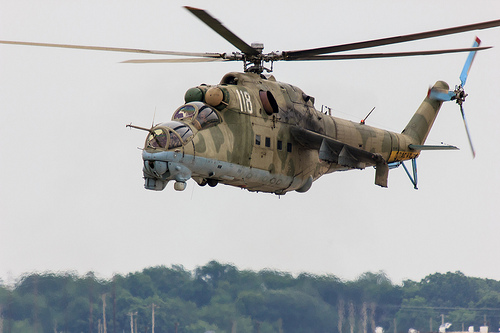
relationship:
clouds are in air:
[0, 3, 500, 292] [2, 1, 495, 278]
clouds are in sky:
[0, 3, 500, 292] [44, 107, 218, 269]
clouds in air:
[0, 3, 500, 292] [2, 1, 495, 278]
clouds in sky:
[0, 3, 500, 292] [390, 197, 460, 239]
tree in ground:
[344, 281, 409, 331] [4, 321, 497, 328]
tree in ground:
[223, 280, 300, 331] [3, 320, 496, 330]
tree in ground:
[85, 279, 122, 331] [0, 325, 493, 332]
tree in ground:
[390, 257, 496, 323] [1, 317, 498, 329]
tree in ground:
[37, 275, 82, 331] [6, 318, 497, 328]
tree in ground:
[363, 270, 387, 332] [6, 318, 497, 328]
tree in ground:
[90, 279, 120, 331] [6, 318, 497, 328]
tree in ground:
[143, 292, 165, 331] [6, 318, 497, 328]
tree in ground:
[473, 288, 498, 331] [6, 318, 497, 328]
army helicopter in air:
[0, 4, 499, 196] [2, 1, 495, 278]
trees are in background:
[0, 259, 498, 331] [1, 263, 498, 331]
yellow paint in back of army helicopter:
[389, 145, 420, 162] [0, 4, 499, 196]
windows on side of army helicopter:
[243, 126, 285, 155] [0, 4, 499, 196]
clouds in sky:
[0, 3, 500, 292] [42, 84, 124, 181]